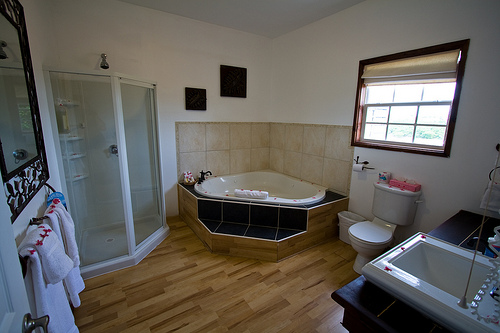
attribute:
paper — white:
[352, 160, 363, 172]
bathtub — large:
[198, 170, 321, 203]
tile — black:
[247, 223, 279, 239]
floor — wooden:
[92, 247, 347, 332]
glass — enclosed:
[66, 70, 149, 273]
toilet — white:
[343, 167, 425, 284]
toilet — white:
[309, 160, 442, 286]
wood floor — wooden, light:
[140, 252, 328, 327]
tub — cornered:
[195, 167, 332, 207]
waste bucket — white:
[336, 204, 368, 253]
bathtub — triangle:
[172, 116, 357, 263]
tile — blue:
[195, 198, 310, 240]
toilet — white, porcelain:
[331, 195, 396, 239]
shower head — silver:
[88, 48, 122, 73]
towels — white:
[20, 196, 85, 330]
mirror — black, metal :
[353, 56, 469, 152]